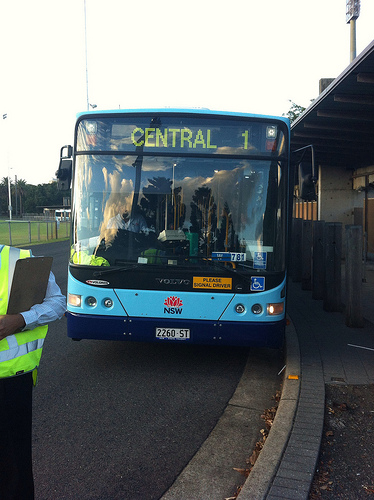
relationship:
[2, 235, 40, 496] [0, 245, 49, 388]
man wearing green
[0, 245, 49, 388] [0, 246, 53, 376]
green bright green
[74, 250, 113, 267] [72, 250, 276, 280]
vest on dash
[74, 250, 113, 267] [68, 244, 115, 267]
vest bright green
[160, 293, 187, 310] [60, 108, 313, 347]
flower on bus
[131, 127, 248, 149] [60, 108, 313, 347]
marquee on bus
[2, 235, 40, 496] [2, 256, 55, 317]
man holding clipbaord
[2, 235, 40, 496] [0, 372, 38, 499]
man wearing pants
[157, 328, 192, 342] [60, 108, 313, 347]
license plate on bus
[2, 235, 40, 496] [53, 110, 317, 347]
man standing in front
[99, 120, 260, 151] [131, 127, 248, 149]
marquee displays marquee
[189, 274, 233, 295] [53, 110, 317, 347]
sticker on bus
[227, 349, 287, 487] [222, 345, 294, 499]
leaves in gutter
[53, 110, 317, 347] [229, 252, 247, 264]
bus number 781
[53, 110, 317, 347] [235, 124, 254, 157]
bus route number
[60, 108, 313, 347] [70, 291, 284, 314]
bus bus lights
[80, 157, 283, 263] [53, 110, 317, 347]
window of bus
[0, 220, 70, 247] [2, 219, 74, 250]
field play field